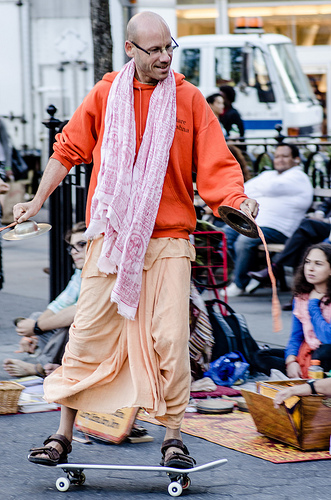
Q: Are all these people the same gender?
A: No, they are both male and female.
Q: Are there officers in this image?
A: No, there are no officers.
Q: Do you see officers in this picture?
A: No, there are no officers.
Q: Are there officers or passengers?
A: No, there are no officers or passengers.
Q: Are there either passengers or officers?
A: No, there are no officers or passengers.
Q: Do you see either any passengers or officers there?
A: No, there are no officers or passengers.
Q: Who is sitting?
A: The man is sitting.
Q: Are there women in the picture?
A: Yes, there is a woman.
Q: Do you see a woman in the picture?
A: Yes, there is a woman.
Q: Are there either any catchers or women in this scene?
A: Yes, there is a woman.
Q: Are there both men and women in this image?
A: Yes, there are both a woman and a man.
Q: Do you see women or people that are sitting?
A: Yes, the woman is sitting.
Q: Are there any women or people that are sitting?
A: Yes, the woman is sitting.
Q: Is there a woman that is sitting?
A: Yes, there is a woman that is sitting.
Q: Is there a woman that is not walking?
A: Yes, there is a woman that is sitting.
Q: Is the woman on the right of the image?
A: Yes, the woman is on the right of the image.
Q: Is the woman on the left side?
A: No, the woman is on the right of the image.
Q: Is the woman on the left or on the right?
A: The woman is on the right of the image.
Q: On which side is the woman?
A: The woman is on the right of the image.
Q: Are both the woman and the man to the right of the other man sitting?
A: Yes, both the woman and the man are sitting.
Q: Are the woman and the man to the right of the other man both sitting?
A: Yes, both the woman and the man are sitting.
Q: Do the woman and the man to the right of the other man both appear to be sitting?
A: Yes, both the woman and the man are sitting.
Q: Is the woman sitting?
A: Yes, the woman is sitting.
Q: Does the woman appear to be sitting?
A: Yes, the woman is sitting.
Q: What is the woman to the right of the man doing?
A: The woman is sitting.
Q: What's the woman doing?
A: The woman is sitting.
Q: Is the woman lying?
A: No, the woman is sitting.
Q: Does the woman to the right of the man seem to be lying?
A: No, the woman is sitting.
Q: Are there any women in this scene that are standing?
A: No, there is a woman but she is sitting.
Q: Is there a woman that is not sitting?
A: No, there is a woman but she is sitting.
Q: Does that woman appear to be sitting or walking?
A: The woman is sitting.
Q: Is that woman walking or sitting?
A: The woman is sitting.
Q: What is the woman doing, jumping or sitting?
A: The woman is sitting.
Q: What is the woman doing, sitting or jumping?
A: The woman is sitting.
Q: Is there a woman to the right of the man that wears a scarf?
A: Yes, there is a woman to the right of the man.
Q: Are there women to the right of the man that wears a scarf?
A: Yes, there is a woman to the right of the man.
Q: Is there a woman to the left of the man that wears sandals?
A: No, the woman is to the right of the man.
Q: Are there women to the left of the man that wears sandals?
A: No, the woman is to the right of the man.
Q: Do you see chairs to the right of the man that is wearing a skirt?
A: No, there is a woman to the right of the man.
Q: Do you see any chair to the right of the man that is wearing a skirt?
A: No, there is a woman to the right of the man.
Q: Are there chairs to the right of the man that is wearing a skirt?
A: No, there is a woman to the right of the man.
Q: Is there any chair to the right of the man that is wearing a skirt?
A: No, there is a woman to the right of the man.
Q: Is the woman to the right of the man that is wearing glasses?
A: Yes, the woman is to the right of the man.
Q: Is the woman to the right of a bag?
A: No, the woman is to the right of the man.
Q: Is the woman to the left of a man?
A: No, the woman is to the right of a man.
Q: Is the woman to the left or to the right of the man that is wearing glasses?
A: The woman is to the right of the man.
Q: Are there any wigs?
A: No, there are no wigs.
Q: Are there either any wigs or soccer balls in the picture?
A: No, there are no wigs or soccer balls.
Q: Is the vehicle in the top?
A: Yes, the vehicle is in the top of the image.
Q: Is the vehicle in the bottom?
A: No, the vehicle is in the top of the image.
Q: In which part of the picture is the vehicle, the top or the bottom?
A: The vehicle is in the top of the image.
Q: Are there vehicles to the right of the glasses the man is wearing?
A: Yes, there is a vehicle to the right of the glasses.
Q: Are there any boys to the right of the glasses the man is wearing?
A: No, there is a vehicle to the right of the glasses.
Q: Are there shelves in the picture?
A: No, there are no shelves.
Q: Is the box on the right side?
A: Yes, the box is on the right of the image.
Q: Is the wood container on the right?
A: Yes, the box is on the right of the image.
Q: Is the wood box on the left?
A: No, the box is on the right of the image.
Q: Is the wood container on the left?
A: No, the box is on the right of the image.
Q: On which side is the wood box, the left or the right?
A: The box is on the right of the image.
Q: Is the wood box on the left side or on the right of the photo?
A: The box is on the right of the image.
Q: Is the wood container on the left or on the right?
A: The box is on the right of the image.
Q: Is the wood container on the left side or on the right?
A: The box is on the right of the image.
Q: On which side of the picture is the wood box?
A: The box is on the right of the image.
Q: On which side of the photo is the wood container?
A: The box is on the right of the image.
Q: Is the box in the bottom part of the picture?
A: Yes, the box is in the bottom of the image.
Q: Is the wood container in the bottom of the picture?
A: Yes, the box is in the bottom of the image.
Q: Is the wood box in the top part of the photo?
A: No, the box is in the bottom of the image.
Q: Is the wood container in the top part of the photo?
A: No, the box is in the bottom of the image.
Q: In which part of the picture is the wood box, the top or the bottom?
A: The box is in the bottom of the image.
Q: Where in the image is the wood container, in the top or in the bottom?
A: The box is in the bottom of the image.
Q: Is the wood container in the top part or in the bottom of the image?
A: The box is in the bottom of the image.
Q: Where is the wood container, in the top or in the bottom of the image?
A: The box is in the bottom of the image.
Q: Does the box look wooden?
A: Yes, the box is wooden.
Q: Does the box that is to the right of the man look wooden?
A: Yes, the box is wooden.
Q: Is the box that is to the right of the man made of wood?
A: Yes, the box is made of wood.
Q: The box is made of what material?
A: The box is made of wood.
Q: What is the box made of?
A: The box is made of wood.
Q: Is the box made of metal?
A: No, the box is made of wood.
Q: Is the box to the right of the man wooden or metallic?
A: The box is wooden.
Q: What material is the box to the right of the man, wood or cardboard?
A: The box is made of wood.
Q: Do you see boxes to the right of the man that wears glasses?
A: Yes, there is a box to the right of the man.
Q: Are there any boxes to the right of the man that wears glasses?
A: Yes, there is a box to the right of the man.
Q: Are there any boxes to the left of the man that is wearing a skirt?
A: No, the box is to the right of the man.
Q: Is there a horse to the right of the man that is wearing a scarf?
A: No, there is a box to the right of the man.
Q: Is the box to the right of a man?
A: Yes, the box is to the right of a man.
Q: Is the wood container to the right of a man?
A: Yes, the box is to the right of a man.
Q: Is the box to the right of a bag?
A: No, the box is to the right of a man.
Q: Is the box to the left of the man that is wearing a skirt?
A: No, the box is to the right of the man.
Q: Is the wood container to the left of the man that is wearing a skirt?
A: No, the box is to the right of the man.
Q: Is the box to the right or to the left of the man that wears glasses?
A: The box is to the right of the man.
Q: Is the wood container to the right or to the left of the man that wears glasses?
A: The box is to the right of the man.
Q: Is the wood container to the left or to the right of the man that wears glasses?
A: The box is to the right of the man.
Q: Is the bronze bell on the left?
A: Yes, the bell is on the left of the image.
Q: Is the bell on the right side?
A: No, the bell is on the left of the image.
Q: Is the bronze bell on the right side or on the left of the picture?
A: The bell is on the left of the image.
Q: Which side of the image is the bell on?
A: The bell is on the left of the image.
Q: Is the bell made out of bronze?
A: Yes, the bell is made of bronze.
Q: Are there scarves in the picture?
A: Yes, there is a scarf.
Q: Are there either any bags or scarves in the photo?
A: Yes, there is a scarf.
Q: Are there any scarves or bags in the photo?
A: Yes, there is a scarf.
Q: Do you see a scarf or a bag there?
A: Yes, there is a scarf.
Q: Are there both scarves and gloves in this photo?
A: No, there is a scarf but no gloves.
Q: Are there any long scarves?
A: Yes, there is a long scarf.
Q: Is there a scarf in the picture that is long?
A: Yes, there is a scarf that is long.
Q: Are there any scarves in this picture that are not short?
A: Yes, there is a long scarf.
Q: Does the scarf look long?
A: Yes, the scarf is long.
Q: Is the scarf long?
A: Yes, the scarf is long.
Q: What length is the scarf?
A: The scarf is long.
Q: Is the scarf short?
A: No, the scarf is long.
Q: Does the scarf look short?
A: No, the scarf is long.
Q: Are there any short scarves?
A: No, there is a scarf but it is long.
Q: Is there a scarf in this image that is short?
A: No, there is a scarf but it is long.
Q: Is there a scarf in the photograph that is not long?
A: No, there is a scarf but it is long.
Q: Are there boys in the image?
A: No, there are no boys.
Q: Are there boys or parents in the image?
A: No, there are no boys or parents.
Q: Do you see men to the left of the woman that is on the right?
A: Yes, there is a man to the left of the woman.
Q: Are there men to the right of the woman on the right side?
A: No, the man is to the left of the woman.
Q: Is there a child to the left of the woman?
A: No, there is a man to the left of the woman.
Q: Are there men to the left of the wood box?
A: Yes, there is a man to the left of the box.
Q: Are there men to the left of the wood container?
A: Yes, there is a man to the left of the box.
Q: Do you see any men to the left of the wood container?
A: Yes, there is a man to the left of the box.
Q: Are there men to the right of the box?
A: No, the man is to the left of the box.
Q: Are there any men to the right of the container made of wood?
A: No, the man is to the left of the box.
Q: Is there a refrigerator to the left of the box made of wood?
A: No, there is a man to the left of the box.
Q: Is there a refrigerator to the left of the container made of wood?
A: No, there is a man to the left of the box.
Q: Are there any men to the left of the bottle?
A: Yes, there is a man to the left of the bottle.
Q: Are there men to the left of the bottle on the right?
A: Yes, there is a man to the left of the bottle.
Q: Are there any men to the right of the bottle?
A: No, the man is to the left of the bottle.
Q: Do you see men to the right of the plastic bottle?
A: No, the man is to the left of the bottle.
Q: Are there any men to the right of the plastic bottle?
A: No, the man is to the left of the bottle.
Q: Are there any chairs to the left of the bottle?
A: No, there is a man to the left of the bottle.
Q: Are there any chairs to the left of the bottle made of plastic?
A: No, there is a man to the left of the bottle.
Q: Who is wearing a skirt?
A: The man is wearing a skirt.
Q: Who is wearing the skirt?
A: The man is wearing a skirt.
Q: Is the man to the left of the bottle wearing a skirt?
A: Yes, the man is wearing a skirt.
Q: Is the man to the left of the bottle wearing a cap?
A: No, the man is wearing a skirt.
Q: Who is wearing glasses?
A: The man is wearing glasses.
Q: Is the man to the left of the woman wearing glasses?
A: Yes, the man is wearing glasses.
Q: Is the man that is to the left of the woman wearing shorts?
A: No, the man is wearing glasses.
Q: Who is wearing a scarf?
A: The man is wearing a scarf.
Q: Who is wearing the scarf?
A: The man is wearing a scarf.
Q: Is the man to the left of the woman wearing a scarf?
A: Yes, the man is wearing a scarf.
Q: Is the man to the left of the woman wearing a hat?
A: No, the man is wearing a scarf.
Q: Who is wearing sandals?
A: The man is wearing sandals.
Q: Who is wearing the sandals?
A: The man is wearing sandals.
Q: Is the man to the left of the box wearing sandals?
A: Yes, the man is wearing sandals.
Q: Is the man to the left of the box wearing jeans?
A: No, the man is wearing sandals.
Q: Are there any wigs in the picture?
A: No, there are no wigs.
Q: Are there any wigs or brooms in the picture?
A: No, there are no wigs or brooms.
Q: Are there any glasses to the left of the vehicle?
A: Yes, there are glasses to the left of the vehicle.